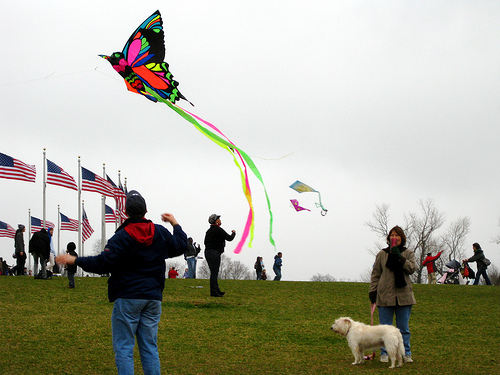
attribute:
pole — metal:
[42, 150, 47, 277]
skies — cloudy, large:
[306, 22, 456, 145]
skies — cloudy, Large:
[3, 7, 496, 280]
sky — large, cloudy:
[276, 20, 493, 161]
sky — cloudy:
[0, 2, 497, 282]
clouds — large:
[6, 20, 498, 276]